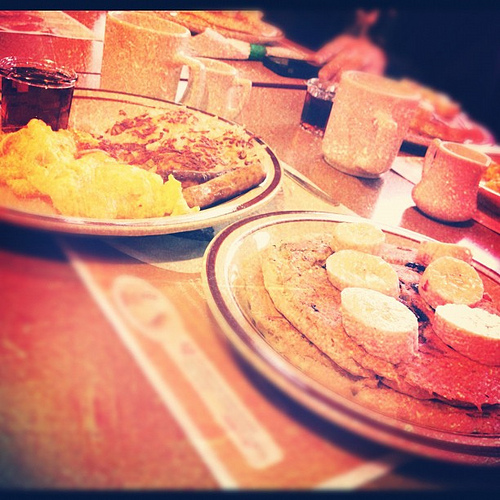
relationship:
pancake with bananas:
[244, 206, 499, 434] [330, 214, 499, 362]